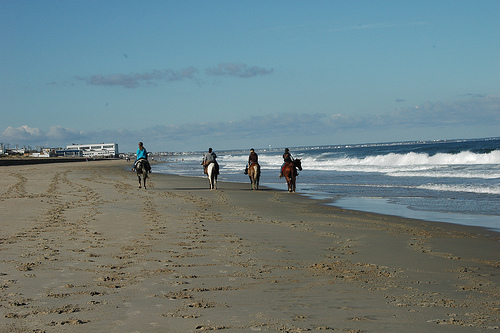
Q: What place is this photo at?
A: It is at the beach.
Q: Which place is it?
A: It is a beach.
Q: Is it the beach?
A: Yes, it is the beach.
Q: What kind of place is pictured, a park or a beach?
A: It is a beach.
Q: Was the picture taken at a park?
A: No, the picture was taken in a beach.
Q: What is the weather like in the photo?
A: It is clear.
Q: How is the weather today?
A: It is clear.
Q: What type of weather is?
A: It is clear.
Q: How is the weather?
A: It is clear.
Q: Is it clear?
A: Yes, it is clear.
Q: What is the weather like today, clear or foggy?
A: It is clear.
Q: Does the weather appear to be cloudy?
A: No, it is clear.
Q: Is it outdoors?
A: Yes, it is outdoors.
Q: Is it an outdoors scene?
A: Yes, it is outdoors.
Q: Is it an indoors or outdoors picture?
A: It is outdoors.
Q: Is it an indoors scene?
A: No, it is outdoors.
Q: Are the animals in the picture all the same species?
A: Yes, all the animals are horses.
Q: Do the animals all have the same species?
A: Yes, all the animals are horses.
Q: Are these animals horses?
A: Yes, all the animals are horses.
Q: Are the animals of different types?
A: No, all the animals are horses.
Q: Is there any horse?
A: Yes, there is a horse.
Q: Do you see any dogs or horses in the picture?
A: Yes, there is a horse.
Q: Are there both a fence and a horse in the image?
A: No, there is a horse but no fences.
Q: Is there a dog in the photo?
A: No, there are no dogs.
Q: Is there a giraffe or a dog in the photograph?
A: No, there are no dogs or giraffes.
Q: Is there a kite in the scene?
A: No, there are no kites.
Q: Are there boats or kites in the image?
A: No, there are no kites or boats.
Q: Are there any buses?
A: No, there are no buses.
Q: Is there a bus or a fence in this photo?
A: No, there are no buses or fences.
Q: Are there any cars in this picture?
A: No, there are no cars.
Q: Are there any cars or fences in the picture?
A: No, there are no cars or fences.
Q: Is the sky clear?
A: Yes, the sky is clear.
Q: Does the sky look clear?
A: Yes, the sky is clear.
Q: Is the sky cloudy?
A: No, the sky is clear.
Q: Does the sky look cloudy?
A: No, the sky is clear.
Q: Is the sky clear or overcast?
A: The sky is clear.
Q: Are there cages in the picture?
A: No, there are no cages.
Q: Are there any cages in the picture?
A: No, there are no cages.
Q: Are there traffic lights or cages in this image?
A: No, there are no cages or traffic lights.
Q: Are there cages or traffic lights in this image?
A: No, there are no cages or traffic lights.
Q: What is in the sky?
A: The clouds are in the sky.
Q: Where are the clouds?
A: The clouds are in the sky.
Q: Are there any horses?
A: Yes, there are horses.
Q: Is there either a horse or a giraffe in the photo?
A: Yes, there are horses.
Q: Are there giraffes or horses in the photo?
A: Yes, there are horses.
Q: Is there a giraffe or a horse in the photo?
A: Yes, there are horses.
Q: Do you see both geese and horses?
A: No, there are horses but no geese.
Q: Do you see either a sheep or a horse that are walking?
A: Yes, the horses are walking.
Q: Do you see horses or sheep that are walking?
A: Yes, the horses are walking.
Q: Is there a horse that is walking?
A: Yes, there are horses that are walking.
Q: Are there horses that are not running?
A: Yes, there are horses that are walking.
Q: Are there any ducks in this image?
A: No, there are no ducks.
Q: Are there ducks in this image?
A: No, there are no ducks.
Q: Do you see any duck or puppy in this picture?
A: No, there are no ducks or puppys.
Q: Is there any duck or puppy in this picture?
A: No, there are no ducks or puppys.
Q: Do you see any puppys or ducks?
A: No, there are no ducks or puppys.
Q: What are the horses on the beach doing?
A: The horses are walking.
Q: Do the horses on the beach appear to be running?
A: No, the horses are walking.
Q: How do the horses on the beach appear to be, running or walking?
A: The horses are walking.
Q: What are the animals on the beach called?
A: The animals are horses.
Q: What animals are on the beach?
A: The animals are horses.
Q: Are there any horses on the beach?
A: Yes, there are horses on the beach.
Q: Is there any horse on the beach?
A: Yes, there are horses on the beach.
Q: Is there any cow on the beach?
A: No, there are horses on the beach.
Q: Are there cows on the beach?
A: No, there are horses on the beach.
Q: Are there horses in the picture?
A: Yes, there is a horse.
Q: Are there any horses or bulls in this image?
A: Yes, there is a horse.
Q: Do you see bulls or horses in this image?
A: Yes, there is a horse.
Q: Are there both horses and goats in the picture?
A: No, there is a horse but no goats.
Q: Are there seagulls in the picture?
A: No, there are no seagulls.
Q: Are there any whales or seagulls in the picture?
A: No, there are no seagulls or whales.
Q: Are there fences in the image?
A: No, there are no fences.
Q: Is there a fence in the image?
A: No, there are no fences.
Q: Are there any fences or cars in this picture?
A: No, there are no fences or cars.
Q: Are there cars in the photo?
A: No, there are no cars.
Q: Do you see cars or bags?
A: No, there are no cars or bags.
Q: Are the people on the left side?
A: Yes, the people are on the left of the image.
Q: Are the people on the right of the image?
A: No, the people are on the left of the image.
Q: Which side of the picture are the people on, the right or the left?
A: The people are on the left of the image.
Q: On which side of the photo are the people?
A: The people are on the left of the image.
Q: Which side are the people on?
A: The people are on the left of the image.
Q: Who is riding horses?
A: The people are riding horses.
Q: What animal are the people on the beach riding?
A: The people are riding horses.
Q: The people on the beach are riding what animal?
A: The people are riding horses.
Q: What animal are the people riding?
A: The people are riding horses.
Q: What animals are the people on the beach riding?
A: The people are riding horses.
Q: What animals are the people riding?
A: The people are riding horses.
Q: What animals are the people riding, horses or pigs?
A: The people are riding horses.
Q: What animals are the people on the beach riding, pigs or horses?
A: The people are riding horses.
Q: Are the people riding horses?
A: Yes, the people are riding horses.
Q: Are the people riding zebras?
A: No, the people are riding horses.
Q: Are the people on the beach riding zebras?
A: No, the people are riding horses.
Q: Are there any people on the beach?
A: Yes, there are people on the beach.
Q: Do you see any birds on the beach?
A: No, there are people on the beach.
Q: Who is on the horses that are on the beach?
A: The people are on the horses.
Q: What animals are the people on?
A: The people are on the horses.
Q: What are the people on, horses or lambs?
A: The people are on horses.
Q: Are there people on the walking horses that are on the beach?
A: Yes, there are people on the horses.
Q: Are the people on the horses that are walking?
A: Yes, the people are on the horses.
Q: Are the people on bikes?
A: No, the people are on the horses.